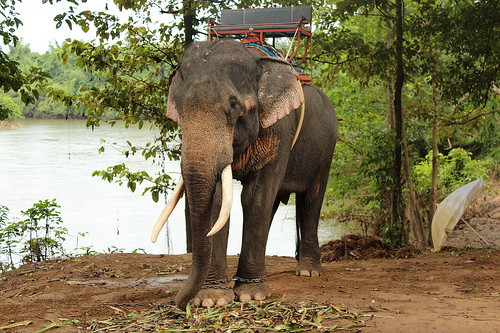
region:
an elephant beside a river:
[146, 21, 423, 304]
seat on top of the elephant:
[210, 3, 362, 80]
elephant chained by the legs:
[200, 253, 269, 293]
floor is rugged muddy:
[406, 270, 475, 332]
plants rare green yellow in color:
[351, 55, 430, 170]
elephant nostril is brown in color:
[178, 110, 225, 192]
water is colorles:
[41, 140, 109, 195]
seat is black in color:
[244, 13, 304, 34]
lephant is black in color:
[249, 108, 331, 168]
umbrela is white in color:
[436, 180, 486, 247]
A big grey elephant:
[152, 46, 364, 306]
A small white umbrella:
[406, 192, 488, 256]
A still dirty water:
[32, 150, 142, 237]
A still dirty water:
[5, 131, 84, 186]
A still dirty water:
[41, 110, 118, 155]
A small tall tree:
[365, 8, 409, 228]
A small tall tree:
[62, 15, 237, 240]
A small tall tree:
[410, 51, 444, 240]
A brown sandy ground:
[365, 242, 456, 331]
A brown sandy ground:
[20, 280, 107, 320]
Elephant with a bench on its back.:
[160, 7, 340, 310]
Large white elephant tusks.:
[143, 162, 235, 244]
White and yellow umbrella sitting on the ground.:
[421, 171, 498, 258]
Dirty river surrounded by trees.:
[3, 86, 422, 266]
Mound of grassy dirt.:
[318, 233, 423, 265]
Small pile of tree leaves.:
[11, 293, 384, 330]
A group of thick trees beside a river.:
[307, 2, 498, 259]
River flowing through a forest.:
[2, 107, 379, 267]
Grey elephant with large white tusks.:
[155, 38, 337, 314]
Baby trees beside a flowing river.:
[1, 199, 82, 276]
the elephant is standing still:
[143, 38, 338, 302]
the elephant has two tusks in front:
[150, 163, 240, 240]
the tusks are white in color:
[152, 165, 239, 242]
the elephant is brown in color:
[160, 42, 337, 302]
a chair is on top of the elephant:
[207, 5, 314, 69]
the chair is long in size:
[205, 3, 314, 63]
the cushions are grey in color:
[215, 6, 310, 30]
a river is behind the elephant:
[0, 107, 405, 273]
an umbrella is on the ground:
[428, 178, 490, 248]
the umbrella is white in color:
[432, 178, 488, 257]